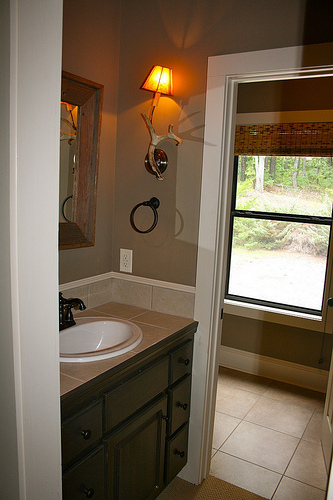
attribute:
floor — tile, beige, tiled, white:
[156, 373, 333, 498]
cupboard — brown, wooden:
[61, 322, 197, 499]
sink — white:
[57, 314, 143, 366]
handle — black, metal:
[128, 198, 165, 235]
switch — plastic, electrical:
[120, 248, 136, 273]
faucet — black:
[57, 290, 86, 330]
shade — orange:
[141, 65, 174, 98]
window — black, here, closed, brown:
[222, 146, 331, 314]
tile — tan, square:
[217, 419, 301, 477]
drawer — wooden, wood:
[167, 339, 194, 390]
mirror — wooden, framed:
[58, 73, 104, 254]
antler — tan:
[142, 106, 180, 178]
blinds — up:
[231, 78, 330, 157]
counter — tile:
[57, 300, 198, 399]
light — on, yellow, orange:
[139, 65, 175, 113]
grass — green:
[226, 246, 329, 312]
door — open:
[206, 76, 331, 497]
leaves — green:
[232, 156, 333, 215]